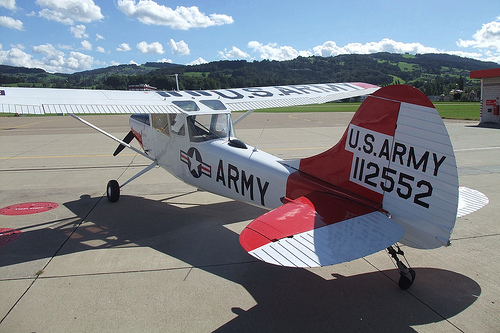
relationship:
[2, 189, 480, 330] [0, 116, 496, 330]
shadow on ground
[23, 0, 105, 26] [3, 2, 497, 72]
cloud in sky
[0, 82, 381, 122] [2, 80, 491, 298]
wing on plane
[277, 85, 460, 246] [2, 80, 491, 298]
tail on plane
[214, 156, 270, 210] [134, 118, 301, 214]
letters on fuselage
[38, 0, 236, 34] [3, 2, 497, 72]
cloud in sky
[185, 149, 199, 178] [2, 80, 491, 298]
star on plane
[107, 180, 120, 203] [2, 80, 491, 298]
wheel on plane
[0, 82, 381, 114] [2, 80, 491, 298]
wing on plane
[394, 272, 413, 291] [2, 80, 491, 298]
wheel mounted on plane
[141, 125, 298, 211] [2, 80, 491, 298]
body belonging to plane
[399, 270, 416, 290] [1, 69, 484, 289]
wheel mounted on plane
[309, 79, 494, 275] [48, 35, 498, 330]
tail of aircraft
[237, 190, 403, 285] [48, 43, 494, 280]
pannel of aircraft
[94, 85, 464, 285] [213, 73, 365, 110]
aircraft has a right wing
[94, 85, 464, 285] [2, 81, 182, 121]
aircraft has a left wing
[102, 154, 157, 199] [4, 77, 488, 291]
landing gear of aircraft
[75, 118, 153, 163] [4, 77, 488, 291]
strut of aircraft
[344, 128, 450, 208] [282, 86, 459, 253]
writing on wing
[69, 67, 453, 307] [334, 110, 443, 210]
plane with lettering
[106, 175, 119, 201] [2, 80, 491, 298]
wheel of plane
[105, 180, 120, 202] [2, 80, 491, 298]
tire of a plane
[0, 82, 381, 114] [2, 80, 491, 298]
wing of a plane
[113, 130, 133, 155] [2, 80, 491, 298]
propeller on a plane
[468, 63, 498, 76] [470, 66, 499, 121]
roof on a building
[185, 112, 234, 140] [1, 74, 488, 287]
window on a airplane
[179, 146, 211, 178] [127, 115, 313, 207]
logo on side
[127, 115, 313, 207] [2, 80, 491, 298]
side of plane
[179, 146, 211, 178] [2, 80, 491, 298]
logo on plane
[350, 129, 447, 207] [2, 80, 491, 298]
letters on plane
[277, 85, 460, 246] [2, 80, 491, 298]
tail of plane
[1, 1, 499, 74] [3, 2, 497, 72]
clouds in sky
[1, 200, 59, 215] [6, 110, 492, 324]
circle on pavement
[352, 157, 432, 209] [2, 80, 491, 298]
112552 on plane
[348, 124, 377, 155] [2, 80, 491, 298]
letters on plane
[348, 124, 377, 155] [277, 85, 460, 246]
letters on tail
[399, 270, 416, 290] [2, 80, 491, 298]
wheel on plane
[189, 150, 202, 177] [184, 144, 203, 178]
star in circle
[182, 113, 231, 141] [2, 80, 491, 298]
windshield on plane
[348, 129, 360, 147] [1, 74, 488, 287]
letter on airplane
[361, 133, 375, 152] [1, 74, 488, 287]
letter on airplane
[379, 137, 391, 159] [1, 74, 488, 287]
letter on airplane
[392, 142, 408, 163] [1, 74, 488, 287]
letter on airplane